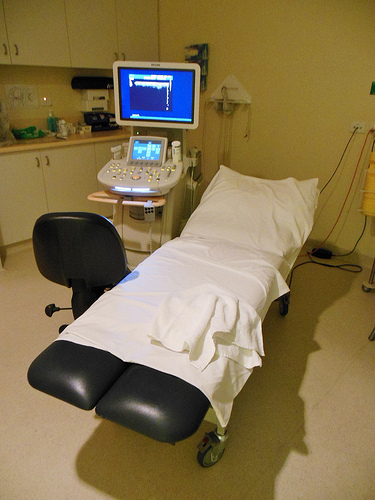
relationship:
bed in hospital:
[102, 170, 273, 372] [56, 23, 360, 113]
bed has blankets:
[102, 170, 273, 372] [146, 230, 291, 289]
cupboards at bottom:
[10, 154, 135, 225] [13, 204, 139, 232]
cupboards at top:
[10, 154, 135, 225] [36, 2, 176, 18]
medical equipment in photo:
[94, 149, 176, 209] [27, 17, 352, 472]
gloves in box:
[176, 46, 220, 96] [176, 44, 214, 58]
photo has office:
[27, 17, 352, 472] [29, 23, 375, 320]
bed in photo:
[102, 170, 273, 372] [27, 17, 352, 472]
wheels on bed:
[188, 423, 247, 474] [102, 170, 273, 372]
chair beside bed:
[30, 196, 131, 311] [102, 170, 273, 372]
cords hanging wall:
[324, 138, 374, 263] [235, 30, 348, 158]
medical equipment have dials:
[94, 149, 176, 209] [112, 161, 138, 176]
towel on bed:
[187, 300, 269, 356] [102, 170, 273, 372]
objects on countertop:
[55, 118, 81, 134] [6, 124, 126, 149]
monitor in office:
[114, 51, 200, 135] [29, 23, 375, 320]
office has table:
[29, 23, 361, 309] [89, 178, 183, 250]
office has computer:
[29, 23, 361, 309] [105, 75, 209, 195]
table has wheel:
[89, 178, 183, 250] [206, 437, 242, 453]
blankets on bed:
[200, 248, 279, 301] [102, 170, 273, 372]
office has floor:
[29, 23, 361, 309] [287, 414, 361, 462]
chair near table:
[30, 196, 131, 311] [89, 178, 183, 250]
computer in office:
[105, 75, 209, 195] [29, 23, 361, 309]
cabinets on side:
[23, 9, 189, 52] [6, 64, 120, 88]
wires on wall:
[334, 135, 353, 259] [235, 30, 348, 158]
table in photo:
[102, 170, 273, 372] [27, 17, 352, 472]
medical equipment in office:
[94, 149, 176, 209] [29, 23, 375, 320]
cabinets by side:
[23, 9, 189, 52] [6, 64, 120, 88]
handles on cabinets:
[2, 45, 22, 57] [23, 9, 189, 52]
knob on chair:
[69, 291, 90, 311] [30, 196, 131, 311]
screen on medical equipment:
[126, 79, 187, 108] [94, 149, 176, 209]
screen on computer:
[126, 79, 187, 108] [105, 75, 209, 195]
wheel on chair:
[54, 314, 70, 337] [30, 196, 131, 311]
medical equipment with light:
[94, 149, 176, 209] [146, 169, 167, 182]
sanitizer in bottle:
[37, 116, 62, 134] [45, 103, 60, 137]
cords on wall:
[324, 138, 374, 263] [235, 30, 348, 158]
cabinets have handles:
[23, 9, 189, 52] [2, 45, 22, 57]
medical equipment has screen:
[94, 149, 176, 209] [126, 79, 187, 108]